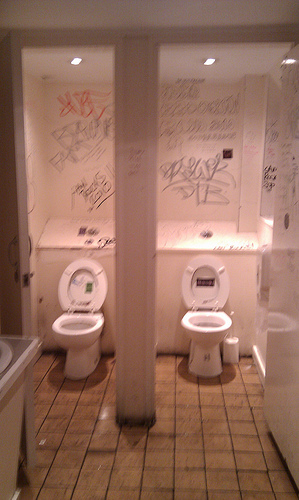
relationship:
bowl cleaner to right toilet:
[222, 310, 239, 362] [180, 251, 231, 376]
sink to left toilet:
[6, 335, 16, 420] [44, 254, 111, 382]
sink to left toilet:
[6, 335, 16, 420] [174, 250, 235, 379]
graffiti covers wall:
[40, 86, 116, 219] [41, 76, 111, 220]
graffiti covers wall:
[159, 84, 239, 205] [158, 73, 263, 355]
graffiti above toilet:
[7, 37, 295, 256] [51, 258, 103, 378]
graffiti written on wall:
[159, 84, 239, 205] [158, 73, 263, 355]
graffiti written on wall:
[48, 90, 116, 211] [36, 81, 113, 350]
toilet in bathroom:
[181, 253, 233, 378] [0, 0, 298, 498]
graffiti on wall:
[159, 84, 239, 205] [18, 30, 298, 221]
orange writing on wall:
[42, 81, 113, 127] [18, 30, 298, 221]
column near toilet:
[115, 41, 158, 425] [180, 251, 231, 376]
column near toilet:
[115, 41, 158, 425] [49, 256, 110, 379]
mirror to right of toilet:
[259, 72, 292, 136] [13, 54, 268, 378]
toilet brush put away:
[230, 309, 237, 339] [186, 313, 267, 421]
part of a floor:
[17, 409, 92, 462] [40, 424, 268, 499]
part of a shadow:
[51, 380, 99, 431] [181, 357, 240, 385]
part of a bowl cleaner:
[55, 366, 251, 446] [223, 310, 239, 363]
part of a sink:
[2, 395, 193, 409] [2, 334, 35, 383]